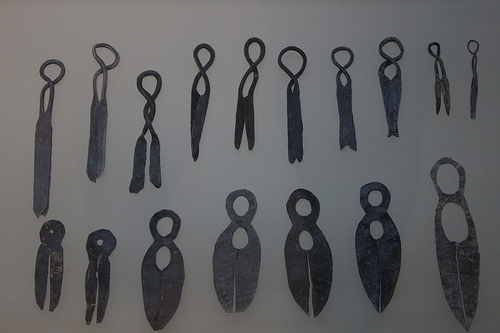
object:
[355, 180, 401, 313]
tool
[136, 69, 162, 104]
metal loop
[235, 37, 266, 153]
drawing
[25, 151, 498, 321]
group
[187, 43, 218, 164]
scissors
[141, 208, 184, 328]
stick person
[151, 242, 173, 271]
chest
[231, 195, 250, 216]
circle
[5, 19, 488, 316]
background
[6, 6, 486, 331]
house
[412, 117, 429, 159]
wall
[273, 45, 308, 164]
antique tool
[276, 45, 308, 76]
loop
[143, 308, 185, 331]
tip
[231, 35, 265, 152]
scissors shears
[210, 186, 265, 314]
scissors shears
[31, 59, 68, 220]
ancient scissors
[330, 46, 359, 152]
objects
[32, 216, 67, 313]
objects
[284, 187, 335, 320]
objects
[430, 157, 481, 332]
objects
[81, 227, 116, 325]
person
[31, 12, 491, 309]
surface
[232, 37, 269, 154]
scissors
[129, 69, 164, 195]
body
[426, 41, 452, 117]
body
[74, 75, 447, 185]
ties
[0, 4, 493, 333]
image